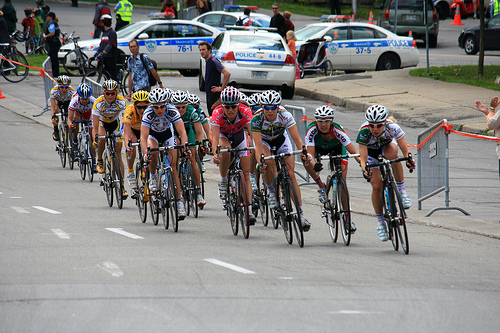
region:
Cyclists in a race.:
[47, 75, 417, 255]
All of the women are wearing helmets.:
[47, 73, 415, 255]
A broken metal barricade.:
[415, 116, 470, 213]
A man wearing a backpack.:
[121, 37, 162, 87]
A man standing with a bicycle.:
[81, 13, 125, 75]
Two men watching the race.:
[122, 39, 229, 85]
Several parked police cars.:
[56, 0, 418, 100]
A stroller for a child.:
[297, 37, 332, 77]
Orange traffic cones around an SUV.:
[347, 0, 464, 50]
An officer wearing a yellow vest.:
[112, 0, 133, 30]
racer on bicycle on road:
[356, 92, 421, 249]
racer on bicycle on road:
[308, 84, 343, 214]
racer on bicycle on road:
[257, 85, 301, 253]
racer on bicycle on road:
[207, 68, 249, 248]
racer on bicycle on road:
[170, 90, 202, 195]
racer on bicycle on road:
[127, 79, 148, 199]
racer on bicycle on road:
[94, 73, 119, 193]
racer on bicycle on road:
[73, 85, 90, 157]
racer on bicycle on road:
[50, 64, 76, 141]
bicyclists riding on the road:
[18, 54, 437, 266]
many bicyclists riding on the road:
[0, 47, 460, 292]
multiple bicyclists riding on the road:
[32, 42, 429, 286]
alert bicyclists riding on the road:
[35, 38, 440, 283]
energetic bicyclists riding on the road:
[30, 42, 459, 272]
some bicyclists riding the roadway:
[22, 34, 444, 300]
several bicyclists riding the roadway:
[41, 50, 438, 287]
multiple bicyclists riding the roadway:
[37, 37, 434, 296]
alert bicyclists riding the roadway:
[31, 51, 451, 285]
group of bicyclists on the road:
[50, 73, 413, 253]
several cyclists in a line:
[51, 76, 415, 256]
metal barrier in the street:
[416, 120, 471, 215]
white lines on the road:
[1, 188, 361, 313]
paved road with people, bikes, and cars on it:
[2, 2, 499, 332]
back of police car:
[208, 30, 293, 87]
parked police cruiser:
[54, 10, 211, 70]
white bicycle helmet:
[365, 103, 389, 123]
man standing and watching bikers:
[198, 43, 231, 118]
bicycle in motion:
[262, 150, 313, 247]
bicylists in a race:
[48, 82, 448, 250]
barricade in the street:
[421, 103, 444, 210]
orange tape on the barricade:
[436, 126, 493, 148]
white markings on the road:
[98, 225, 329, 314]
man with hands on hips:
[194, 34, 225, 97]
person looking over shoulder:
[92, 5, 114, 78]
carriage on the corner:
[297, 34, 338, 77]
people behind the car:
[236, 7, 294, 28]